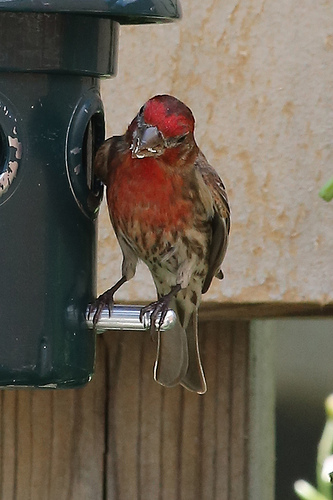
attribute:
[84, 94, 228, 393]
bird — brown, red, sitting, perched, standing, spotted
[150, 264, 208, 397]
tail — long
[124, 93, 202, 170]
head — tilted, red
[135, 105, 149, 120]
eye — black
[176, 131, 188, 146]
eye — black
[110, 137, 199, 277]
chest — red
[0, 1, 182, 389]
feeder — gray, metal, worn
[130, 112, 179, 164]
beak — open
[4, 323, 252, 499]
slats — wood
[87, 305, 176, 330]
pole — silver